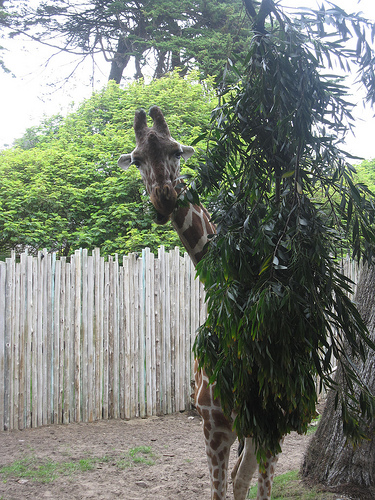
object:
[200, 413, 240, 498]
legs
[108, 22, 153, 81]
bark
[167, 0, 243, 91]
tree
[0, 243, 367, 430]
fence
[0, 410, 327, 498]
ground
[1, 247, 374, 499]
enclosure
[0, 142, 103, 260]
tree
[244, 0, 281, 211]
branch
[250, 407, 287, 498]
legs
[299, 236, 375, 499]
bark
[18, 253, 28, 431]
logs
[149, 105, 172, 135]
antlers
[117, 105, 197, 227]
head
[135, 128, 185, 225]
face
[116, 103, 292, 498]
giraffe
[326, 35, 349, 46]
leaf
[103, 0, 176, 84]
tree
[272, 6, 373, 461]
branch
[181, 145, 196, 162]
ear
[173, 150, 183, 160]
eye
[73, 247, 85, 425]
wood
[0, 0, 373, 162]
sky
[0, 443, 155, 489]
grass